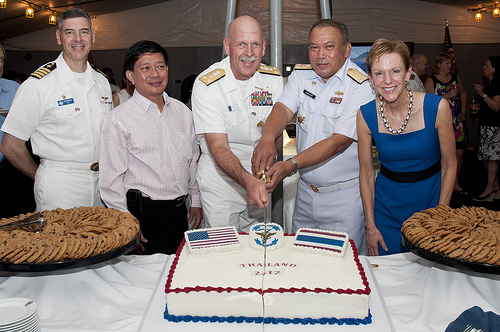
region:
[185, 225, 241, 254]
an American flag on a cake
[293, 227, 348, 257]
a blue red and white flag on a cake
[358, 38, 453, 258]
a woman wearing a blue dress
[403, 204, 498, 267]
a large platter of cookies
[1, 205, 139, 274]
a platter of chocolate chip cookies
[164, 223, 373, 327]
a red white and blue cake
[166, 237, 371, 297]
red border on a large cake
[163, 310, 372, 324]
blue border on a cake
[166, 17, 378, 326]
two men cutting a large red white and blue cake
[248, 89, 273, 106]
ribbons on a military uniform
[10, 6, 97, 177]
man wearing white shirt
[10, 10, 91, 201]
man wearing white pants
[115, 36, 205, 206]
man wearing pink shirt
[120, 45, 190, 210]
man wearing black pants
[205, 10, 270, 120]
man wearing white shirt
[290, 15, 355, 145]
man wearing white shirt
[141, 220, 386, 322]
cake on a table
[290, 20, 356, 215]
man wearing white pants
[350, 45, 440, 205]
woman wearing blue dress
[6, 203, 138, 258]
cookies on a table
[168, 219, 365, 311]
the cake is large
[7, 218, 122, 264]
cookies on a tray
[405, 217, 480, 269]
cookies on a tray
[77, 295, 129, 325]
tablecloth on a table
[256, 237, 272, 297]
the cake is being cut into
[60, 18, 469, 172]
a group of people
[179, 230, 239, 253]
american flag on cake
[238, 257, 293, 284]
writing on the cake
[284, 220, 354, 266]
flag on the cake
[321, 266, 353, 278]
the frosting is white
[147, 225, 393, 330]
Red white and blue sheet cake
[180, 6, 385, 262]
Two men cutting into cake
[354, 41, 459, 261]
Woman in black and blue dress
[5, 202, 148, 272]
Tray full of cookies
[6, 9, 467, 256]
Group of people smiling at camera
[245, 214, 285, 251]
Blue and white logo on cake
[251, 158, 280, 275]
Silver knive for cake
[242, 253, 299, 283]
Red lettering on cake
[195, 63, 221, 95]
Brown shoulder patch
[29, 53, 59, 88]
Black and gold military patch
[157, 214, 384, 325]
a large white cake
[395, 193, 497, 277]
a large plate of cookies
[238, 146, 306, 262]
hands holding a knife cutting a cake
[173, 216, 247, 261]
an american flag on a cake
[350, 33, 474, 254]
a woman in a blue dress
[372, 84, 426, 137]
a necklace being worn by a woman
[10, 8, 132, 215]
a man wearing a uniform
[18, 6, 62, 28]
light fixtures in the ceiling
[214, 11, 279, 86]
a man with a bald head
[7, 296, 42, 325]
a stack of white plates